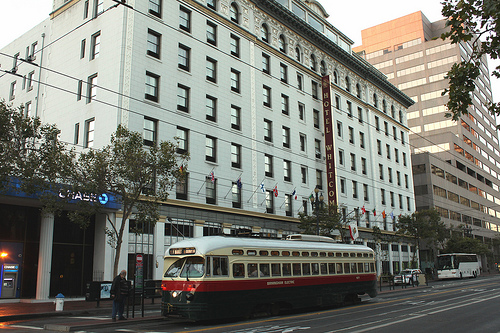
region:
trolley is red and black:
[231, 232, 370, 300]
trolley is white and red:
[193, 248, 329, 293]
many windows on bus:
[241, 253, 353, 260]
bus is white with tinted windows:
[437, 263, 498, 285]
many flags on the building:
[211, 152, 318, 207]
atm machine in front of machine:
[0, 234, 35, 306]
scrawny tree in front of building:
[94, 129, 155, 329]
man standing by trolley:
[107, 252, 126, 325]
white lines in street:
[380, 303, 437, 323]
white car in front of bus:
[396, 263, 428, 305]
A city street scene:
[5, 18, 493, 323]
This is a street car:
[151, 216, 386, 325]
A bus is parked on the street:
[431, 245, 488, 285]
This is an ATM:
[1, 261, 23, 300]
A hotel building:
[106, 2, 422, 277]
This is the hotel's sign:
[313, 65, 343, 217]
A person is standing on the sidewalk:
[106, 266, 133, 322]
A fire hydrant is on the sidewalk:
[49, 288, 72, 317]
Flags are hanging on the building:
[141, 154, 413, 229]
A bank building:
[4, 169, 117, 306]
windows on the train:
[206, 258, 321, 274]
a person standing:
[110, 270, 131, 305]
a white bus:
[436, 248, 485, 280]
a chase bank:
[7, 178, 109, 210]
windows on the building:
[143, 74, 253, 132]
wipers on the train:
[179, 263, 194, 280]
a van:
[395, 268, 418, 280]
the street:
[383, 300, 448, 332]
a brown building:
[411, 51, 458, 134]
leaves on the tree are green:
[447, 66, 472, 110]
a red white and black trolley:
[156, 234, 381, 328]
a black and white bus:
[430, 250, 480, 278]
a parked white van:
[393, 269, 422, 286]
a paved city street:
[92, 270, 497, 329]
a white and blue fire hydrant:
[51, 293, 66, 311]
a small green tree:
[80, 134, 186, 311]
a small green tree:
[401, 207, 456, 287]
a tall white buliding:
[0, 4, 422, 296]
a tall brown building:
[352, 8, 499, 266]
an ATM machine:
[0, 264, 20, 295]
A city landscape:
[4, 2, 497, 322]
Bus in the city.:
[157, 220, 374, 326]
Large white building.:
[15, 2, 422, 234]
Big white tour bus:
[420, 245, 488, 285]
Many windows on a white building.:
[143, 2, 420, 227]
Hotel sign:
[314, 70, 344, 212]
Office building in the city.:
[349, 16, 495, 237]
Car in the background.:
[386, 260, 437, 297]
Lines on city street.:
[227, 290, 494, 332]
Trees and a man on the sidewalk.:
[2, 93, 175, 330]